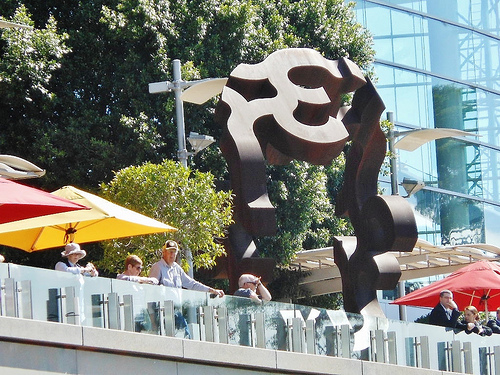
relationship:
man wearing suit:
[430, 287, 477, 335] [431, 302, 466, 333]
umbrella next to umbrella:
[0, 172, 89, 225] [0, 184, 178, 253]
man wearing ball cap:
[145, 239, 225, 299] [161, 237, 181, 253]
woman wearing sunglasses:
[116, 254, 162, 286] [132, 263, 143, 272]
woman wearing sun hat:
[53, 239, 97, 280] [60, 241, 88, 261]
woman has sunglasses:
[116, 254, 162, 286] [132, 263, 143, 272]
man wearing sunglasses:
[232, 273, 274, 305] [248, 280, 259, 288]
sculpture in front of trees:
[184, 42, 417, 324] [0, 0, 395, 313]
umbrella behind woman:
[0, 172, 89, 225] [53, 239, 97, 280]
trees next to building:
[0, 0, 395, 313] [340, 1, 499, 331]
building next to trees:
[340, 1, 499, 331] [0, 0, 395, 313]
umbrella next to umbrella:
[0, 184, 178, 253] [0, 172, 89, 225]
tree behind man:
[94, 156, 237, 275] [145, 239, 225, 299]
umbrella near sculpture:
[0, 184, 178, 253] [184, 42, 417, 324]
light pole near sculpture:
[169, 57, 194, 177] [184, 42, 417, 324]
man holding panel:
[145, 239, 225, 299] [208, 293, 295, 358]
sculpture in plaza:
[184, 42, 417, 324] [6, 17, 498, 362]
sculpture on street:
[184, 42, 417, 324] [6, 273, 496, 373]